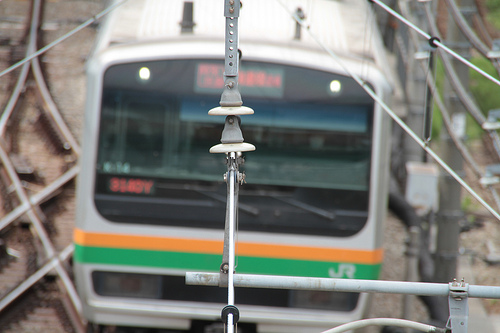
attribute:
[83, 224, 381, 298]
stripes — orange, green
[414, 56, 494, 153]
grass — green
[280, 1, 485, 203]
cable — metal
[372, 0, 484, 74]
cable — metal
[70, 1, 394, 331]
train — silver, blurry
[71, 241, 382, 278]
stripe — green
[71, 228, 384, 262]
stripe — yellow, orange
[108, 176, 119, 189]
number — red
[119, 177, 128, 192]
number — red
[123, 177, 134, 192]
number — red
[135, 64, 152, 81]
light — white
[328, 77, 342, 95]
light — white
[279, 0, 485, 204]
wire — silver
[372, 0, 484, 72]
wire — silver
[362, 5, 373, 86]
wire — silver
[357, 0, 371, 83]
wire — silver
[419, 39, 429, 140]
wire — silver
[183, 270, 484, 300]
pole — gray